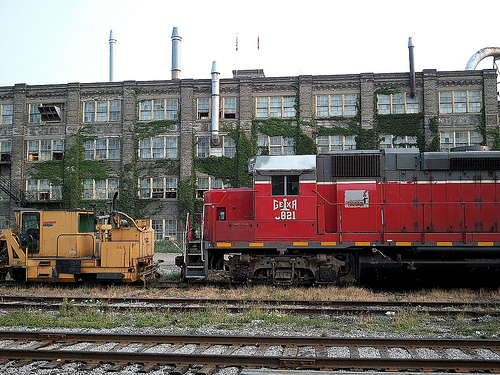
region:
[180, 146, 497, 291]
Red and black train car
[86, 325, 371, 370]
Train tracks in gravel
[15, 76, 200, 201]
Building partially covered in kudzu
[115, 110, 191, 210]
Green ivy growing up a wall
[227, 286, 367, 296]
Dry grass area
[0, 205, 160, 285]
Yellow construction vehicle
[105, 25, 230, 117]
Multiple exhaust stacks on building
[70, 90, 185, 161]
Windows on outside of building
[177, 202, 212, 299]
Metal steps leading out to grass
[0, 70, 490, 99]
Decorative cornice on top of brick building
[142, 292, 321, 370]
two sets of train tracks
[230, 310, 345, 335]
green weeds in gravel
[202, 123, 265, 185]
green ivy on building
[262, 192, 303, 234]
white logo on red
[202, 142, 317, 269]
engine on front of train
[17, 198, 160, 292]
green machinery on train tracks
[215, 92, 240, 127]
open window on building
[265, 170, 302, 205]
windows on train engine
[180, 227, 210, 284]
steps on front of train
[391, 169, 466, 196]
white line on train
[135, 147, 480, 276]
Red train sitting on track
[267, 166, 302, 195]
Window on side of train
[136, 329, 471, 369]
Train track is rusted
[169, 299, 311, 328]
Grass growing between tracks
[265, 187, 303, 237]
White wording on side of train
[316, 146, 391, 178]
Vent in top of train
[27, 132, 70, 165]
Windows on side of building are broken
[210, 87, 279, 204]
Moss growing on side of building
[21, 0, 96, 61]
Sky is blue with white clouds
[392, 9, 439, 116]
Smoke stack on top of building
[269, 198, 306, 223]
white lettering on a red train engine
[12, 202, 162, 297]
a yellow train car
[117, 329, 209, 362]
old rusty railroad tracks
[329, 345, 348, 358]
gray gravel between the tracks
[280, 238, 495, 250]
black and yellow line on the train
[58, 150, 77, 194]
green ivy growing on a wall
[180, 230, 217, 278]
black metal stairs on the train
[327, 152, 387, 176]
a vent on the side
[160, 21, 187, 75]
a white smoke stack above the building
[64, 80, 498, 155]
windows in the building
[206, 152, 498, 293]
black and red train car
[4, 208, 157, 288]
yellow train construction vehicle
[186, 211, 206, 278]
metal stairs on train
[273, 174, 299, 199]
window on train car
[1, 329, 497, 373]
metal and wood train tracks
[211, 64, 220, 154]
metal smoke stack on building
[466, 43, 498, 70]
grey metal exhaust pipe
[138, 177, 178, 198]
glass windows on building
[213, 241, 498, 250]
reflector bars on train